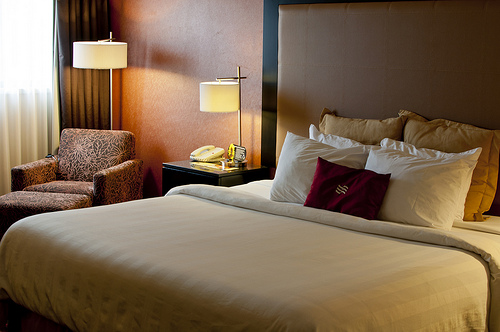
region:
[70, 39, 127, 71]
cream lamp near wall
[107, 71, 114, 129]
metal rod holding the lamp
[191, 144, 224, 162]
white color phone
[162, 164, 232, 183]
black color table placed near bed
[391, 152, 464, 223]
white color pillow kept on bed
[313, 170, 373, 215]
dark purple color pillow kept in center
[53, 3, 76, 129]
brown color curtain near window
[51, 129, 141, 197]
printed sofa chair for relaxing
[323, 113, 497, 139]
cream color pillow kept on bed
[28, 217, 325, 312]
white blanket with stripes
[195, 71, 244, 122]
the desk lamp shade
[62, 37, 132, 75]
the floor lamp shade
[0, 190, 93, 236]
the multi colored ottoman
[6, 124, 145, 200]
the multi colored arm chair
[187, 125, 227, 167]
the telephone on the nightstand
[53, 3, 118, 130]
the dark brown curtain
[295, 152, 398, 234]
the deep red pillow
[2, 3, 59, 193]
the white sheer curtain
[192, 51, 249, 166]
the lamp on the desk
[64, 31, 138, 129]
the lamp on the floor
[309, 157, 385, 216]
moroon pillow on bed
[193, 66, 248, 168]
lamp on nightstand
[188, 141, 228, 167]
phone on nightstand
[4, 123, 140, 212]
chair with foot rest in corner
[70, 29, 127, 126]
lamp behing chair in corner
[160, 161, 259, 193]
dark colored night stand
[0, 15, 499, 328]
a well decorated hotel room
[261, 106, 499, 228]
pillows at head of made bed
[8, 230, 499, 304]
bedspread on bed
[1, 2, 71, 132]
window with curtains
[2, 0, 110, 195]
The curtains colors are white and brown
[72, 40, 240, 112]
Lamp sheds are white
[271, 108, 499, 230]
Pillows on the bed colors are tan,white, and red voliet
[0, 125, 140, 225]
Chair and ottoman are pink, and brown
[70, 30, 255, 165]
Two lamps are in this room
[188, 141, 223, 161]
The phone is white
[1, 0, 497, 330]
Large bed with brown head board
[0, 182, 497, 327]
White striped blanket with sheets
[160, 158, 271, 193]
Black end table with drawers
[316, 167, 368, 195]
this is a pillow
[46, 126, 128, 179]
this is a chair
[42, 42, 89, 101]
this is a curtain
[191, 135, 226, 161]
this is a telephone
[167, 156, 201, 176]
this is a table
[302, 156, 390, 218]
pillow on the hotel bed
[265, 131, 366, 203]
pillow on the hotel bed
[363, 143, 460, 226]
pillow on the hotel bed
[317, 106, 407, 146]
pillow on the hotel bed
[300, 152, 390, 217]
pillow on the hotel bed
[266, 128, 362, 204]
pillow on the hotel bed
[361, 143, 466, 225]
pillow on the hotel bed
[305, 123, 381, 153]
pillow on the hotel bed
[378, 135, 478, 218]
pillow on the hotel bed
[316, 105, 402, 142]
pillow on the hotel bed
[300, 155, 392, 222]
pillow on the hotel bed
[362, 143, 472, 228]
pillow on the hotel bed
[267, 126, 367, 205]
pillow on the hotel bed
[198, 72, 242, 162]
small white bedside lamp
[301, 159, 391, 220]
small burgundy pillow on top of bed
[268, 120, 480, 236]
white pillows on top of double bed